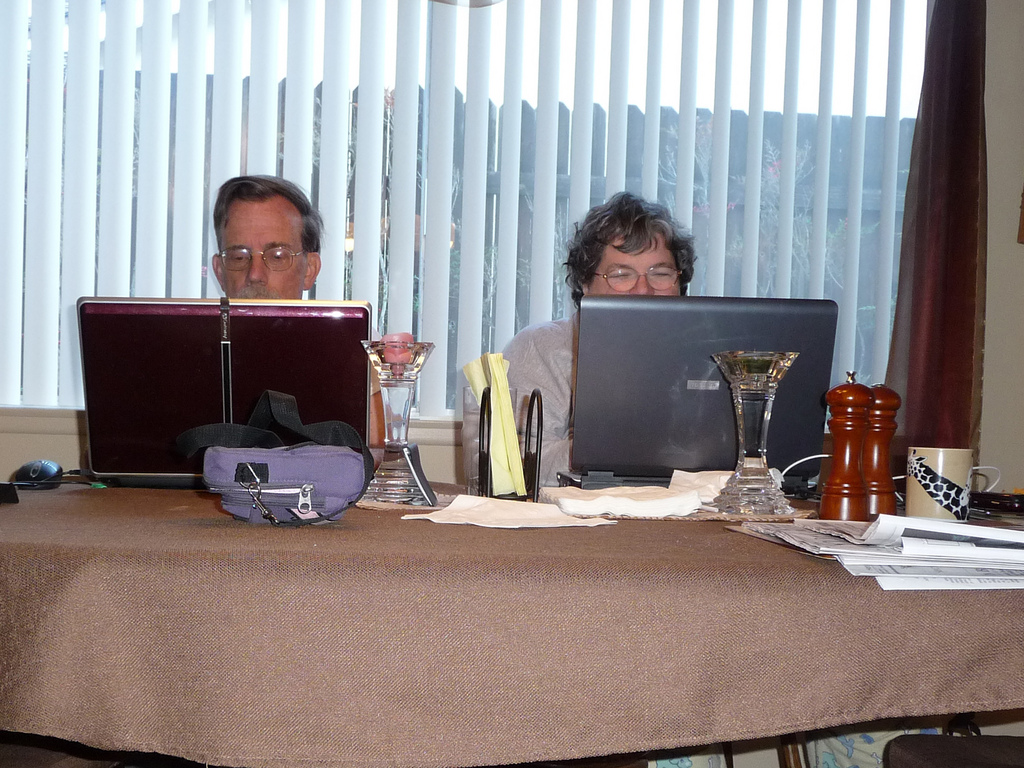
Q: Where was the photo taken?
A: Office.